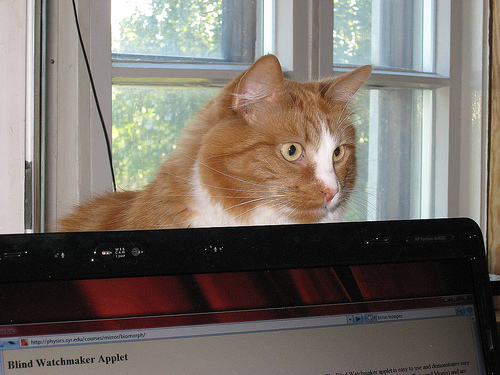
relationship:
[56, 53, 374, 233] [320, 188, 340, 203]
cat has nose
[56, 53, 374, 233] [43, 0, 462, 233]
cat in front of window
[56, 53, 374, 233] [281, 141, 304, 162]
cat has eye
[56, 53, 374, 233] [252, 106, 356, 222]
cat has face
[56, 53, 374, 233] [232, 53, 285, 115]
cat has ear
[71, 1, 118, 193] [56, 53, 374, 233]
wire behind cat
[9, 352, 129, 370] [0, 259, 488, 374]
words on front of computer screen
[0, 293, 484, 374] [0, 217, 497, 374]
webpage open on computer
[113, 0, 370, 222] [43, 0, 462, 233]
tree outside window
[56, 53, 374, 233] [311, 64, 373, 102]
cat has ear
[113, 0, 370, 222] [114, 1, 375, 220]
tree has leaves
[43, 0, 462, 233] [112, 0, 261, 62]
window has window pane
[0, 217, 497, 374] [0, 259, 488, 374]
computer has computer screen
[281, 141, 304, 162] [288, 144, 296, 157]
eye has pupil